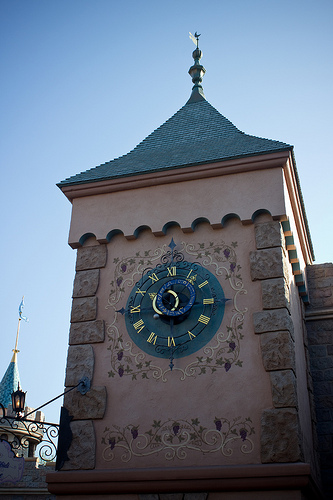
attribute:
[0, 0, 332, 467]
clear sky — blue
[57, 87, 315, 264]
roof — copper, small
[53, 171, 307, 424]
building — stone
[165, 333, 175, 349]
numeral 6 — golden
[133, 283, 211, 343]
clock — outdoor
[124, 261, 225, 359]
clock — outdoor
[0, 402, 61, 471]
metal scrooll — black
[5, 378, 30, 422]
lanter — black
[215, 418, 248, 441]
grapes — purple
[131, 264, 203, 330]
clock — decorative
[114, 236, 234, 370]
clock — teal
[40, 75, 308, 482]
tower — clock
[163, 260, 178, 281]
numeral — roman, brass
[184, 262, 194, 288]
numeral — roman, brass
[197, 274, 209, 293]
numeral — roman, brass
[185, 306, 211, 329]
numeral — roman, brass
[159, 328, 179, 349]
numeral — roman, brass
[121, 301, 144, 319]
numeral — roman, brass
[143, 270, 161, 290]
numeral — roman, brass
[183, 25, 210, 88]
top — decorative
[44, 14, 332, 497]
building — beige